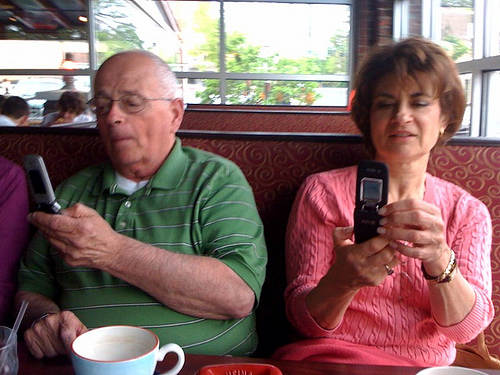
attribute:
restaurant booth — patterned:
[237, 140, 311, 200]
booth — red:
[217, 128, 325, 219]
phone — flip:
[13, 154, 63, 217]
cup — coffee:
[71, 320, 188, 372]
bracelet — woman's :
[417, 248, 466, 286]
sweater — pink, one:
[285, 166, 497, 369]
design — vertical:
[386, 266, 396, 360]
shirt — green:
[11, 139, 261, 368]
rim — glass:
[0, 321, 32, 361]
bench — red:
[2, 127, 497, 369]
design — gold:
[450, 146, 497, 190]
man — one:
[15, 45, 269, 363]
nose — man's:
[110, 103, 126, 124]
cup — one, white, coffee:
[61, 320, 189, 373]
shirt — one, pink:
[299, 167, 492, 373]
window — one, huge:
[5, 6, 495, 125]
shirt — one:
[43, 155, 269, 346]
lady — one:
[290, 40, 492, 362]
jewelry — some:
[380, 250, 457, 280]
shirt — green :
[54, 150, 264, 360]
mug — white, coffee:
[69, 316, 181, 373]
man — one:
[40, 57, 257, 349]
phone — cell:
[23, 147, 83, 269]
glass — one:
[1, 298, 37, 370]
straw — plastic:
[4, 300, 36, 338]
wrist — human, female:
[428, 245, 468, 288]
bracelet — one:
[424, 246, 459, 289]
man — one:
[46, 49, 269, 359]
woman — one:
[299, 32, 494, 367]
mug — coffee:
[67, 322, 179, 372]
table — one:
[24, 335, 437, 373]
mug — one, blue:
[68, 310, 190, 370]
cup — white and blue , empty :
[69, 325, 180, 374]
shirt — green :
[28, 146, 274, 362]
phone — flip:
[351, 159, 390, 245]